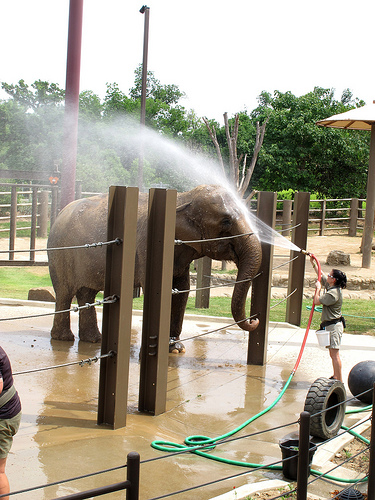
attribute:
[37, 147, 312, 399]
elephant — gray, head, trunk, eye, leg, ear, being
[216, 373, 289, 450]
hose — green, red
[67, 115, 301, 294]
water — spraying, air, hose, fallen, sprinkler, jet, bouncing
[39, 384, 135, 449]
shadow — ground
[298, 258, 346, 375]
lady — wearing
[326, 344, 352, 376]
leg — back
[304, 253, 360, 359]
woman — leg, wearing, holding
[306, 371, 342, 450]
tire — black, standing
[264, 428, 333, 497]
bucket — black, side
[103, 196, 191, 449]
pillar — erected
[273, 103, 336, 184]
tree — green, branches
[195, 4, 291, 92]
sky — white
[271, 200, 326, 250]
fence — wire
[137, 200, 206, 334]
post — metal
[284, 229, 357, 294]
rock — large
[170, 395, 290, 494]
pipe — coiled